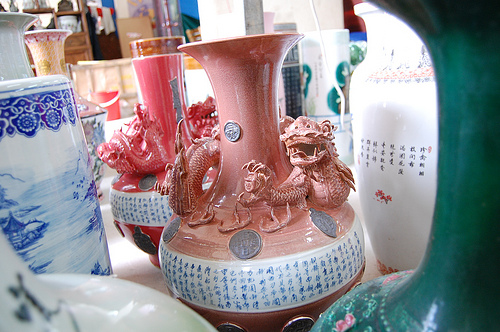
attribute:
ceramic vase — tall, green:
[171, 37, 389, 246]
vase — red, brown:
[160, 33, 365, 330]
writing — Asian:
[356, 137, 431, 176]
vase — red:
[105, 46, 217, 273]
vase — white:
[68, 56, 399, 290]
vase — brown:
[116, 24, 406, 326]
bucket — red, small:
[89, 87, 129, 122]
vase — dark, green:
[355, 3, 440, 279]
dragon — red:
[107, 122, 174, 176]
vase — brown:
[169, 42, 360, 291]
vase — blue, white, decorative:
[17, 60, 80, 279]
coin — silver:
[226, 229, 262, 261]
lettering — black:
[149, 230, 369, 315]